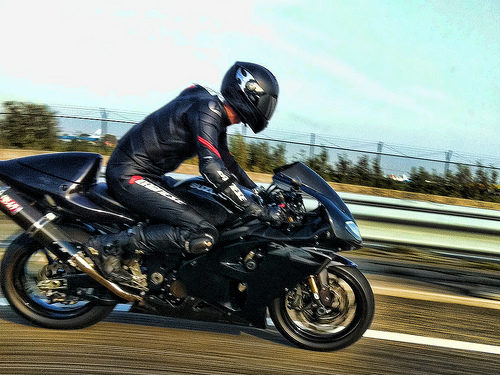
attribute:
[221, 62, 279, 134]
helmet — black, silver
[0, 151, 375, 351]
motorcycle — shiny, modern, great, black, sleek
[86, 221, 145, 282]
right boot — black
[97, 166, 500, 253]
guard rail — metal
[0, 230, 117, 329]
rear tire — moving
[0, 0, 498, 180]
sky — blue